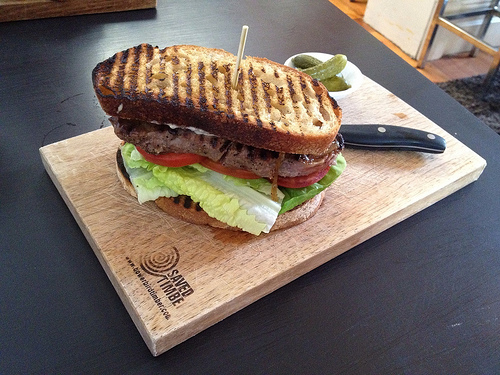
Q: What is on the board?
A: Food.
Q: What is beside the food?
A: Utensil.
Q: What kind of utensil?
A: Knife.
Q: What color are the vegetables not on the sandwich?
A: Green.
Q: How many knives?
A: One.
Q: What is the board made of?
A: Wood.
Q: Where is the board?
A: On the table.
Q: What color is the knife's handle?
A: Black.